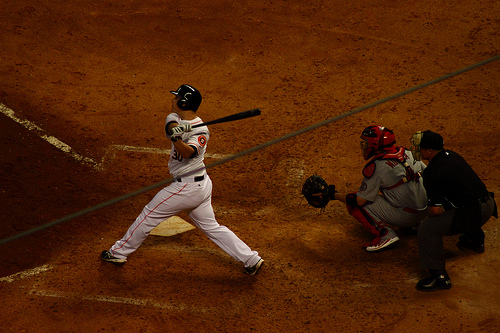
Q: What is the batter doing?
A: Swinging.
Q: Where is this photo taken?
A: Baseball game.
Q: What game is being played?
A: Baseball.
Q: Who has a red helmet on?
A: Catcher.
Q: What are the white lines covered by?
A: Dirt.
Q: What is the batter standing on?
A: Dirt.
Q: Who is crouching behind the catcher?
A: Umpire.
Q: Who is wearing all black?
A: Umpire.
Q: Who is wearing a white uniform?
A: Hitter.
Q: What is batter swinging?
A: Black bat.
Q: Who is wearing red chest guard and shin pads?
A: The catcher.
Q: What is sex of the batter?
A: A man.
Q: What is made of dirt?
A: The playing ground.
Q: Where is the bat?
A: In the guys hands.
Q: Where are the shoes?
A: On the ground.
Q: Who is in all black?
A: The umpire.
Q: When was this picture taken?
A: During a game.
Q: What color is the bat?
A: Black.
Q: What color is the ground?
A: Brown.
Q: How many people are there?
A: Three.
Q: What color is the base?
A: White.